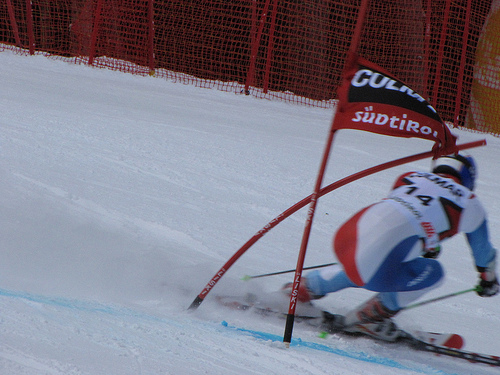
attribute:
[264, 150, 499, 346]
person — skiing, competitive, leaning into course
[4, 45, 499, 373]
slope — snow covered, white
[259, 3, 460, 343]
ski flag — red, lettered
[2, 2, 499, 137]
mesh — orange, red, in background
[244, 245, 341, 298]
left ski pole — long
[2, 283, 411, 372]
line — blue, aqua blue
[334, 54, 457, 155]
flag — red, long, white, black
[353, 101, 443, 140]
word — white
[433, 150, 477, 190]
helmet — blue, white, red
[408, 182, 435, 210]
number — black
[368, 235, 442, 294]
design — blue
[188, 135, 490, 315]
pole — red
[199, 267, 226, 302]
letters — white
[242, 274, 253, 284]
tip — bright green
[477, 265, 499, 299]
glove — black, white, red